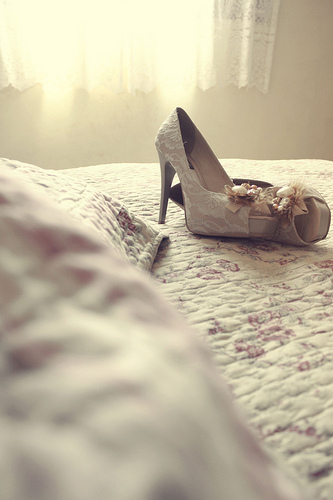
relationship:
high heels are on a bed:
[157, 106, 332, 247] [2, 156, 332, 448]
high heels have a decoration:
[157, 106, 332, 247] [233, 184, 313, 220]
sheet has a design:
[39, 158, 330, 499] [223, 257, 258, 278]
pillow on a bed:
[1, 152, 174, 279] [2, 156, 332, 448]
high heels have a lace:
[157, 106, 332, 247] [190, 184, 227, 241]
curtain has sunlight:
[17, 6, 278, 100] [31, 14, 267, 174]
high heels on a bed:
[157, 106, 332, 247] [2, 156, 332, 448]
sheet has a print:
[39, 158, 330, 499] [206, 259, 246, 280]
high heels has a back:
[157, 106, 332, 247] [158, 118, 179, 223]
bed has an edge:
[2, 156, 332, 448] [8, 158, 331, 169]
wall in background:
[12, 2, 331, 166] [6, 0, 332, 148]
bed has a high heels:
[2, 156, 332, 448] [157, 106, 332, 247]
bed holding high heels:
[2, 156, 332, 448] [157, 106, 332, 247]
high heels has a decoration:
[157, 106, 332, 247] [233, 184, 313, 220]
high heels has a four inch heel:
[157, 106, 332, 247] [157, 152, 175, 225]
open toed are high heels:
[295, 195, 331, 245] [157, 106, 332, 247]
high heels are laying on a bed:
[157, 106, 332, 247] [2, 156, 332, 448]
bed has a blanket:
[2, 156, 332, 448] [9, 161, 332, 498]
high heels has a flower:
[157, 106, 332, 247] [227, 184, 263, 205]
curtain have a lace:
[17, 6, 278, 100] [190, 184, 227, 241]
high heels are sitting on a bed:
[157, 106, 332, 247] [2, 156, 332, 448]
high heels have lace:
[157, 106, 332, 247] [190, 184, 227, 241]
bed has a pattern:
[2, 156, 332, 448] [126, 199, 332, 482]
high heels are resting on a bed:
[157, 106, 332, 247] [2, 156, 332, 448]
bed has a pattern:
[2, 156, 332, 448] [232, 243, 332, 411]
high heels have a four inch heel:
[157, 106, 332, 247] [157, 152, 175, 225]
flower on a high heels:
[227, 184, 263, 205] [157, 106, 332, 247]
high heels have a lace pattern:
[157, 106, 332, 247] [226, 184, 261, 235]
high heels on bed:
[157, 106, 332, 247] [2, 156, 332, 448]